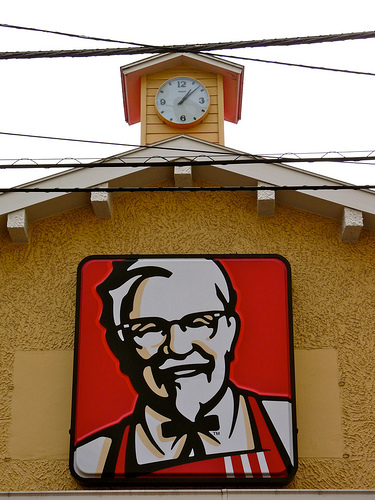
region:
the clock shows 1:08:
[156, 76, 233, 144]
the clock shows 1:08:
[149, 78, 209, 129]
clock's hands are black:
[166, 85, 200, 108]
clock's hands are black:
[172, 75, 193, 104]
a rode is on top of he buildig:
[38, 30, 335, 75]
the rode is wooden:
[42, 34, 328, 66]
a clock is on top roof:
[157, 70, 229, 169]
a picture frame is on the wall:
[85, 224, 370, 498]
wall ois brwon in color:
[195, 199, 289, 243]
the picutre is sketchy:
[94, 257, 266, 481]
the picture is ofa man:
[99, 257, 260, 469]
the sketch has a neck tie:
[159, 415, 233, 450]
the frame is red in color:
[122, 263, 259, 473]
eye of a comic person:
[134, 308, 166, 343]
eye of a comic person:
[175, 305, 211, 339]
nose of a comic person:
[156, 329, 203, 363]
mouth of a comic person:
[164, 351, 217, 382]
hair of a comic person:
[114, 263, 170, 292]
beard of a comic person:
[173, 390, 208, 432]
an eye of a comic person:
[137, 316, 164, 346]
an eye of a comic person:
[193, 312, 215, 331]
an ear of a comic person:
[218, 310, 250, 347]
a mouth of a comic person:
[167, 351, 218, 389]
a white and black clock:
[133, 38, 263, 167]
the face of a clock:
[153, 81, 208, 129]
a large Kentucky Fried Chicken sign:
[63, 239, 308, 485]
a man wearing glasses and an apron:
[80, 251, 288, 474]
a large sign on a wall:
[49, 234, 355, 490]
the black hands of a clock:
[159, 79, 200, 108]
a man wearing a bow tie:
[104, 259, 250, 461]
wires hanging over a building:
[6, 15, 374, 220]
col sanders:
[87, 264, 287, 477]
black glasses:
[108, 305, 246, 366]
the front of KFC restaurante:
[4, 3, 374, 487]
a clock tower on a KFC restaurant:
[110, 40, 255, 151]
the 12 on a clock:
[174, 75, 187, 91]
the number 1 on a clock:
[189, 79, 197, 87]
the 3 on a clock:
[196, 93, 206, 105]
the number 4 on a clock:
[199, 106, 208, 114]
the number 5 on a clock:
[190, 113, 198, 126]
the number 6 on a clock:
[178, 112, 188, 122]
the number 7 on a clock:
[166, 114, 175, 123]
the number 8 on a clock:
[158, 107, 166, 119]